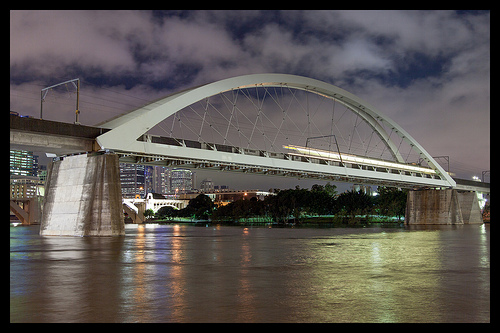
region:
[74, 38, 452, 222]
white bridge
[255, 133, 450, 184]
train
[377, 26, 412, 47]
white clouds in blue sky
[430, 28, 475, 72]
white clouds in blue sky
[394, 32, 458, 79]
white clouds in blue sky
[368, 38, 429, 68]
white clouds in blue sky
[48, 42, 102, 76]
white clouds in blue sky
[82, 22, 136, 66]
white clouds in blue sky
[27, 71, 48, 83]
white clouds in blue sky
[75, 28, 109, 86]
white clouds in blue sky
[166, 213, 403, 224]
Green lighting along trees.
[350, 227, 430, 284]
Beautiful light reflecting off water.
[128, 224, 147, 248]
Orange lighting reflecting on water.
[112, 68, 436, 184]
Arch over freeway bridge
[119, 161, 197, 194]
Downtown buildings in the background.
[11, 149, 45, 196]
Buildings lit with many windows.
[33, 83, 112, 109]
Electrical wires crossing over bridge.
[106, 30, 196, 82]
White and dark blue sky.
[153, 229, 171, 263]
Bluish purple light reflecting off of water.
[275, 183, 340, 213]
Lush trees in the darkness.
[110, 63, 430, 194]
A large curving bridge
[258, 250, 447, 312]
A body of water reflecting light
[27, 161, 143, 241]
A wide support for a bridge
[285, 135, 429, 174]
A speeding train moving over a bridge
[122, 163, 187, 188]
Several city buildings with lit windows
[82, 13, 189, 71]
A portion of sky with wispy clouds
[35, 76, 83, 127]
A metal structure over a bridge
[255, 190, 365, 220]
A line of dark trees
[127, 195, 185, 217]
A distant stone bridge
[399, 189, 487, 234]
Two cement bridge supports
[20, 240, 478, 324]
water under the bridge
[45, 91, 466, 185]
a bridge above the water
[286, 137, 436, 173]
a train on the bridge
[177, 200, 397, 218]
trees next to the water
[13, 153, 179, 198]
buildings in the distance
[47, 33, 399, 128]
the sky above the water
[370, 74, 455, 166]
clouds in the sky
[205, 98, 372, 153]
wires on the bridge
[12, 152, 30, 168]
lights on a building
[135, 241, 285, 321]
reflections in the water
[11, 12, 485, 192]
Fluffy clouds in a dark sky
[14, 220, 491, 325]
Grayish water reflecting city lights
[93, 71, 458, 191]
The arch of a bridge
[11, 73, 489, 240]
A large bridge over gray water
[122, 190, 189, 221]
A bridge over the water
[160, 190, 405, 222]
A group of trees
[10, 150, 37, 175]
Illuminated windows of a building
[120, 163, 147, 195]
Illuminated windows of a building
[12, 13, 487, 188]
Fluffy clouds in the sky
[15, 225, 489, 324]
Water reflecting the city lights